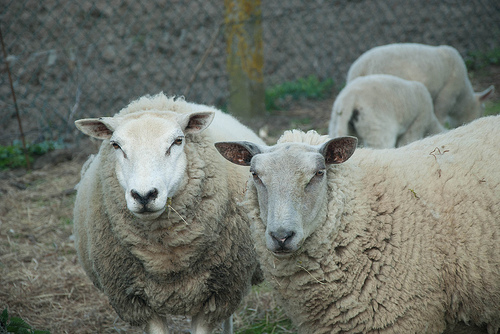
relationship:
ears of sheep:
[57, 99, 110, 153] [384, 198, 449, 247]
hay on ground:
[12, 242, 49, 299] [67, 47, 106, 72]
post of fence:
[226, 5, 259, 67] [42, 23, 187, 43]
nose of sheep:
[272, 229, 288, 244] [384, 198, 449, 247]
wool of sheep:
[189, 165, 228, 226] [384, 198, 449, 247]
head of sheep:
[122, 107, 182, 217] [384, 198, 449, 247]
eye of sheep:
[110, 130, 132, 160] [384, 198, 449, 247]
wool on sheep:
[189, 165, 228, 226] [384, 198, 449, 247]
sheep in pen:
[384, 198, 449, 247] [72, 63, 434, 261]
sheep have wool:
[384, 198, 449, 247] [189, 165, 228, 226]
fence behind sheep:
[42, 23, 187, 43] [384, 198, 449, 247]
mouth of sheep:
[142, 210, 152, 220] [384, 198, 449, 247]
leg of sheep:
[127, 309, 175, 322] [384, 198, 449, 247]